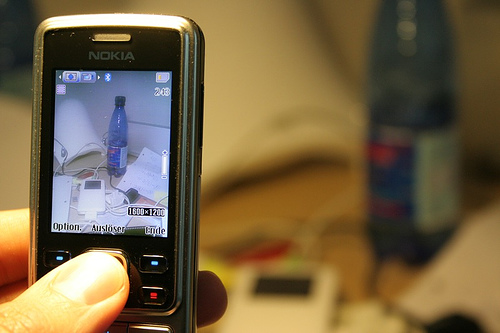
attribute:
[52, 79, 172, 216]
screen — lcd, part, small, white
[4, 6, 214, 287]
phone — smart, cell, part, old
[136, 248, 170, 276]
button — red, end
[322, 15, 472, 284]
bottle — blurry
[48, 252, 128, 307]
finger — pressing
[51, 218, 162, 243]
option — written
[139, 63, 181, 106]
life — battery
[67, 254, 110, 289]
nail — thumb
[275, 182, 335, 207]
counter — top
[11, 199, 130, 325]
person — taking, sending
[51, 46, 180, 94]
device — charging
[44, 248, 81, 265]
key — pad